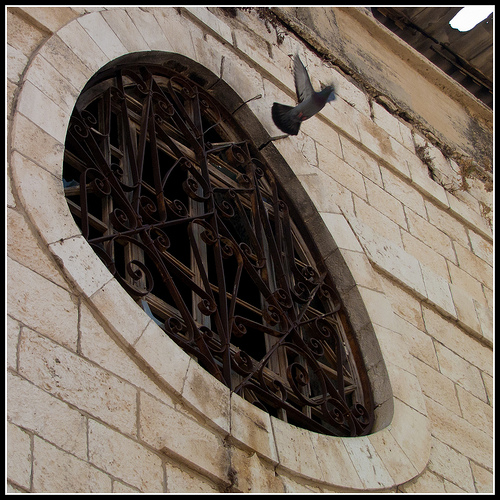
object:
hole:
[449, 5, 489, 33]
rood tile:
[448, 24, 491, 62]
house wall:
[0, 7, 499, 500]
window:
[60, 52, 376, 440]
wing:
[288, 50, 315, 102]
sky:
[448, 4, 491, 33]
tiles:
[427, 52, 458, 80]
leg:
[296, 110, 304, 119]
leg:
[295, 115, 307, 122]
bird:
[269, 41, 339, 136]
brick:
[361, 177, 409, 235]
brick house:
[0, 5, 499, 499]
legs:
[297, 107, 302, 118]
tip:
[292, 47, 300, 59]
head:
[320, 82, 334, 97]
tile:
[410, 7, 462, 37]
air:
[351, 3, 498, 271]